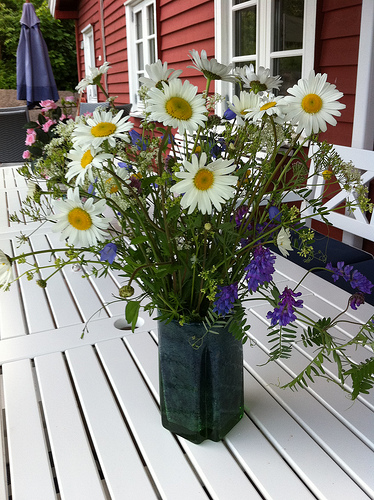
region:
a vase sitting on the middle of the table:
[149, 314, 246, 438]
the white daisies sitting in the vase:
[31, 59, 368, 308]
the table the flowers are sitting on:
[0, 158, 371, 491]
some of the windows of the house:
[216, 2, 315, 110]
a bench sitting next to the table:
[257, 141, 373, 298]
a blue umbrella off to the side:
[14, 0, 59, 110]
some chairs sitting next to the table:
[0, 103, 132, 150]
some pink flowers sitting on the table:
[19, 89, 84, 169]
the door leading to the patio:
[79, 28, 98, 104]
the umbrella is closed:
[10, 5, 69, 101]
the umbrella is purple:
[7, 0, 71, 109]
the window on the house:
[220, 0, 308, 89]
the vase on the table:
[129, 305, 255, 439]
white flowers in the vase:
[136, 58, 211, 134]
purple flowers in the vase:
[195, 242, 327, 338]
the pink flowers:
[16, 94, 87, 133]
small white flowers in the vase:
[102, 147, 174, 219]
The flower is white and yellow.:
[68, 107, 136, 156]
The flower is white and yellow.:
[59, 136, 115, 191]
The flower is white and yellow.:
[43, 182, 121, 255]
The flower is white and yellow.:
[164, 150, 238, 217]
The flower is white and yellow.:
[141, 76, 209, 136]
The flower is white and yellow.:
[277, 69, 345, 137]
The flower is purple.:
[208, 279, 240, 323]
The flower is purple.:
[267, 283, 313, 335]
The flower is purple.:
[306, 256, 372, 295]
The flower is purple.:
[225, 242, 282, 294]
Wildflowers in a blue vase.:
[32, 57, 335, 451]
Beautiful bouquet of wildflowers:
[40, 47, 357, 385]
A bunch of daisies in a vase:
[46, 46, 353, 347]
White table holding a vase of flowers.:
[2, 158, 372, 480]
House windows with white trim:
[117, 1, 168, 112]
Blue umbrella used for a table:
[7, 0, 63, 105]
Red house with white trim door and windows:
[46, 4, 373, 138]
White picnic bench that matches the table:
[303, 143, 371, 264]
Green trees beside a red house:
[1, 2, 83, 92]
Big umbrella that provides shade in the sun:
[11, 1, 63, 109]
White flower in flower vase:
[170, 153, 237, 214]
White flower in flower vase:
[275, 67, 349, 136]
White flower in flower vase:
[49, 186, 113, 250]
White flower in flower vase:
[141, 75, 209, 136]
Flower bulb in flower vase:
[211, 281, 239, 315]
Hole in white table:
[115, 315, 142, 329]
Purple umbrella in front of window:
[13, 1, 61, 105]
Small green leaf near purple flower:
[122, 299, 141, 322]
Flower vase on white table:
[0, 46, 373, 444]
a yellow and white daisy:
[160, 148, 240, 218]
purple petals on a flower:
[240, 241, 280, 298]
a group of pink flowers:
[2, 88, 72, 166]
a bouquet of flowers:
[10, 38, 372, 442]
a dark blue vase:
[150, 313, 260, 446]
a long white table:
[2, 147, 372, 491]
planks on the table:
[7, 357, 156, 495]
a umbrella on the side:
[6, 2, 67, 123]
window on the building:
[105, 6, 174, 114]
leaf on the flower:
[264, 301, 299, 363]